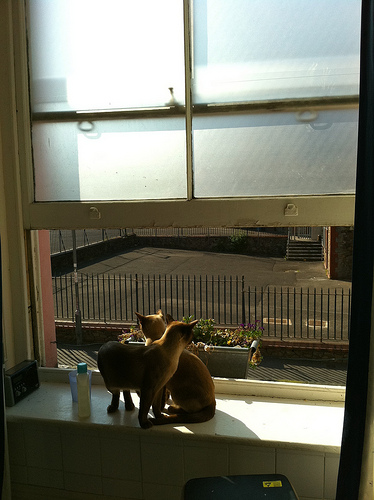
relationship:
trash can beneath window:
[173, 467, 304, 499] [24, 13, 355, 388]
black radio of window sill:
[8, 352, 53, 390] [38, 354, 107, 383]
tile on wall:
[274, 449, 323, 498] [8, 419, 335, 497]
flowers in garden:
[166, 318, 254, 352] [155, 285, 266, 376]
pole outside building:
[69, 227, 83, 345] [8, 86, 341, 444]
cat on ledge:
[97, 314, 199, 429] [32, 370, 340, 461]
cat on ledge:
[133, 308, 216, 426] [32, 370, 340, 461]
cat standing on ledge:
[97, 314, 199, 429] [9, 352, 341, 498]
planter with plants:
[116, 313, 263, 378] [180, 318, 253, 352]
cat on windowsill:
[97, 314, 199, 429] [191, 419, 335, 454]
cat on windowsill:
[133, 308, 216, 426] [191, 419, 335, 454]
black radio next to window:
[5, 358, 41, 409] [1, 1, 361, 401]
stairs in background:
[285, 237, 325, 261] [75, 229, 361, 284]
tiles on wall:
[4, 413, 337, 498] [8, 419, 335, 497]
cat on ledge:
[95, 308, 197, 419] [32, 370, 340, 461]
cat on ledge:
[142, 334, 215, 423] [32, 370, 340, 461]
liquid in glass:
[66, 367, 91, 398] [66, 367, 94, 403]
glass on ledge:
[66, 367, 94, 403] [3, 377, 344, 452]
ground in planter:
[306, 126, 318, 152] [187, 341, 257, 377]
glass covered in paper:
[42, 233, 312, 291] [29, 1, 177, 104]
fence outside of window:
[48, 275, 349, 334] [33, 198, 341, 368]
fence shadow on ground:
[55, 347, 346, 383] [255, 352, 343, 379]